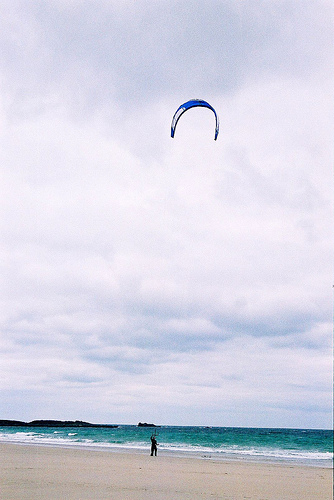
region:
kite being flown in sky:
[164, 89, 223, 156]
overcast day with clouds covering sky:
[75, 200, 231, 296]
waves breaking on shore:
[186, 437, 330, 468]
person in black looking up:
[146, 431, 160, 460]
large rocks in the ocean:
[2, 415, 162, 430]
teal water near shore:
[187, 431, 292, 443]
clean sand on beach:
[22, 456, 125, 497]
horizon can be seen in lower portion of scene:
[187, 417, 326, 447]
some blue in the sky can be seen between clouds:
[105, 325, 304, 351]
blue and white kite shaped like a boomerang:
[160, 86, 234, 153]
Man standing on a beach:
[142, 433, 167, 457]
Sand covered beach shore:
[3, 435, 333, 497]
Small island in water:
[134, 420, 161, 429]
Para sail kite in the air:
[164, 90, 226, 143]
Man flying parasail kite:
[131, 88, 227, 456]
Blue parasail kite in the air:
[166, 98, 225, 139]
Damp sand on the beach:
[4, 437, 329, 468]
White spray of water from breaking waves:
[1, 429, 329, 461]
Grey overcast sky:
[5, 6, 333, 428]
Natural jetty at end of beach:
[1, 416, 118, 431]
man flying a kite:
[142, 414, 174, 466]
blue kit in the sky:
[145, 77, 245, 176]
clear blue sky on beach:
[6, 155, 318, 354]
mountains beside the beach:
[0, 413, 162, 433]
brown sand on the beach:
[0, 456, 332, 498]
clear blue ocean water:
[0, 413, 332, 471]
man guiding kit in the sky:
[145, 419, 178, 460]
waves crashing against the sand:
[1, 430, 329, 465]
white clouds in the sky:
[1, 256, 318, 372]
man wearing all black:
[144, 426, 171, 465]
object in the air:
[146, 70, 253, 150]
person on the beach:
[134, 420, 170, 464]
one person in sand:
[131, 429, 173, 469]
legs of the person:
[144, 447, 161, 459]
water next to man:
[208, 430, 254, 455]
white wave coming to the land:
[188, 440, 225, 458]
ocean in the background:
[244, 411, 289, 437]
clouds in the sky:
[206, 383, 272, 419]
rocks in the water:
[55, 393, 115, 427]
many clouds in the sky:
[33, 126, 145, 223]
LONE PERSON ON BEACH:
[123, 421, 192, 473]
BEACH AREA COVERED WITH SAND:
[4, 441, 332, 492]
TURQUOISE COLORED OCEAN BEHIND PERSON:
[3, 418, 332, 468]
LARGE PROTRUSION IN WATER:
[123, 405, 171, 433]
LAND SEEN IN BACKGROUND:
[1, 411, 124, 442]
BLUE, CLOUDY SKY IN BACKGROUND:
[6, 304, 332, 430]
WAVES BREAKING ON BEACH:
[9, 430, 332, 469]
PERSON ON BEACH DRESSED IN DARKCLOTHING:
[143, 432, 167, 466]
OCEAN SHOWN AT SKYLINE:
[3, 413, 330, 463]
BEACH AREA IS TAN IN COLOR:
[3, 465, 328, 495]